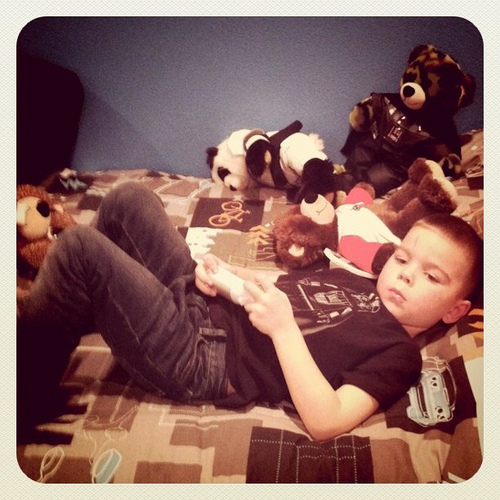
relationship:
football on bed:
[43, 164, 98, 196] [17, 120, 483, 482]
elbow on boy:
[300, 409, 337, 442] [25, 182, 480, 439]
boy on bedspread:
[25, 182, 480, 439] [18, 132, 485, 482]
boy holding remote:
[25, 182, 480, 439] [197, 250, 267, 308]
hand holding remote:
[188, 249, 225, 300] [197, 250, 267, 308]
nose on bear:
[402, 85, 414, 97] [337, 42, 479, 182]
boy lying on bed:
[25, 182, 480, 439] [17, 120, 483, 482]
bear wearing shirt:
[273, 155, 459, 275] [333, 186, 401, 271]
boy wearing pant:
[25, 182, 480, 439] [17, 182, 223, 402]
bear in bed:
[203, 118, 340, 206] [17, 120, 483, 482]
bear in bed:
[203, 118, 340, 206] [1, 127, 499, 498]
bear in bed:
[337, 42, 477, 197] [1, 127, 499, 498]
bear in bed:
[273, 155, 459, 275] [1, 127, 499, 498]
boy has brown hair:
[25, 182, 480, 439] [410, 212, 482, 299]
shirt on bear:
[324, 187, 408, 277] [273, 155, 459, 275]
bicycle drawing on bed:
[208, 202, 252, 229] [34, 162, 481, 428]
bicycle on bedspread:
[208, 198, 252, 229] [19, 125, 490, 482]